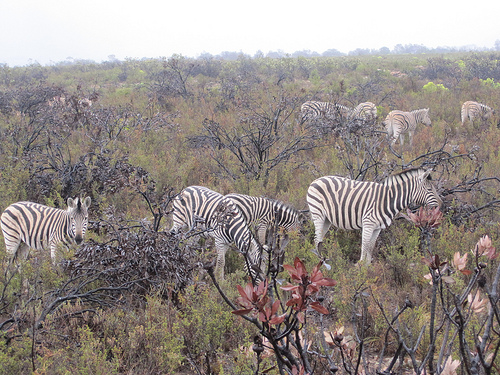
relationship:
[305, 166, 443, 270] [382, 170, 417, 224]
zebra has zebra neck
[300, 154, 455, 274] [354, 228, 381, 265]
zebra has leg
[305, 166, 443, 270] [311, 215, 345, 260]
zebra has leg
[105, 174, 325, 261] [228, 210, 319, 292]
zebra has head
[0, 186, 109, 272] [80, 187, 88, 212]
zebra has ear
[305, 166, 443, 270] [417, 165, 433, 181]
zebra has ear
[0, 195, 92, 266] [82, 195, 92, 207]
zebra has ear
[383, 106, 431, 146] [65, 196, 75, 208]
zebra has ear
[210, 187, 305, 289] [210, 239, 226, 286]
zebra has leg